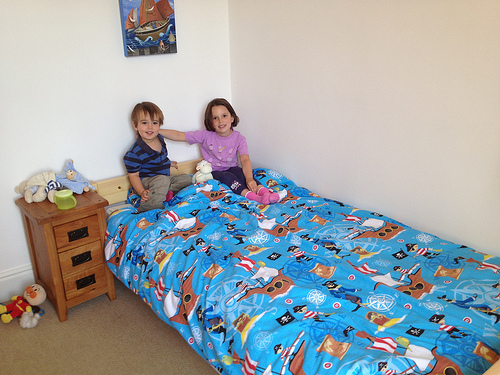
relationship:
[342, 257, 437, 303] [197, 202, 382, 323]
design printed on cloth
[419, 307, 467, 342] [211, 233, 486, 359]
pirate design printed on cloth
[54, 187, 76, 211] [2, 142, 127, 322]
tea cup on dresser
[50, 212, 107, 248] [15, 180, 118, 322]
drawer on dresser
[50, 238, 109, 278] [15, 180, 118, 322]
drawer on dresser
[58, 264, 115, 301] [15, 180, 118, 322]
drawer on dresser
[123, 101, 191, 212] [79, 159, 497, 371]
boy sitting on bed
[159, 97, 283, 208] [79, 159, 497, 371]
girl sitting on bed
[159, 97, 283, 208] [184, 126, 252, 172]
girl wearing purple shirt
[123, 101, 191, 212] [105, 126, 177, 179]
boy wearing shirt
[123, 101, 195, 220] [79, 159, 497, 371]
boy sitting on bed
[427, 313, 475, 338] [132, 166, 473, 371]
pirate design on cloth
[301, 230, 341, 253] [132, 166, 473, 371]
pirates on cloth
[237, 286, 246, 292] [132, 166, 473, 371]
pirates on cloth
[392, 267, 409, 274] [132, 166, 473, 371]
pirates on cloth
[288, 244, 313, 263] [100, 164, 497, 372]
pirate printed on cloth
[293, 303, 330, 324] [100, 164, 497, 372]
pirate printed on cloth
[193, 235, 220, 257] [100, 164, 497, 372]
pirate printed on cloth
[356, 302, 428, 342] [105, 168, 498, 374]
boat on bed cover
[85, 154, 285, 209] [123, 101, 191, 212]
bed head behind boy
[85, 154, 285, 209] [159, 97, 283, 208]
bed head behind girl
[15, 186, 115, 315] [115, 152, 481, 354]
dresser beside bed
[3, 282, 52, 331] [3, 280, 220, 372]
stuffed duck on ground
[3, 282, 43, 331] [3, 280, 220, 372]
duck on ground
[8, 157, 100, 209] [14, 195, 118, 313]
animals on dresser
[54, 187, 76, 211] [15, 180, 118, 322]
tea cup on dresser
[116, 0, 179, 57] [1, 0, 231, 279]
photo on wall